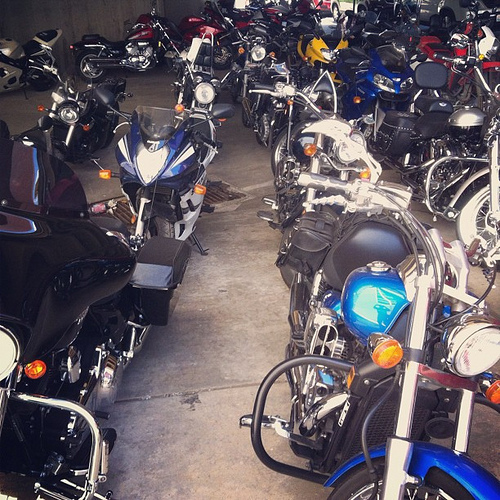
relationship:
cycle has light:
[94, 88, 237, 257] [336, 136, 366, 163]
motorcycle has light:
[214, 36, 282, 97] [312, 47, 346, 63]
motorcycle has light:
[74, 21, 179, 70] [187, 82, 226, 105]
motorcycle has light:
[35, 87, 125, 145] [54, 103, 80, 126]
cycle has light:
[94, 88, 237, 257] [187, 82, 226, 105]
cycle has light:
[94, 88, 237, 257] [245, 44, 270, 64]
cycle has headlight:
[94, 88, 237, 257] [342, 135, 356, 171]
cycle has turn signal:
[94, 88, 237, 257] [93, 167, 116, 185]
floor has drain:
[233, 130, 251, 153] [212, 178, 251, 207]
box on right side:
[276, 211, 336, 278] [341, 68, 362, 95]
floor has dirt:
[233, 130, 251, 153] [214, 236, 245, 282]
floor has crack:
[233, 130, 251, 153] [244, 174, 262, 195]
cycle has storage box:
[94, 88, 237, 257] [377, 98, 422, 153]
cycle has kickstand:
[94, 88, 237, 257] [191, 239, 211, 259]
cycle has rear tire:
[94, 88, 237, 257] [74, 49, 108, 78]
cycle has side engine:
[94, 88, 237, 257] [431, 141, 465, 170]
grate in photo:
[200, 177, 221, 216] [11, 8, 497, 489]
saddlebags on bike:
[401, 108, 450, 137] [9, 25, 69, 91]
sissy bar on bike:
[283, 168, 386, 206] [9, 25, 69, 91]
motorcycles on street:
[87, 29, 423, 204] [219, 133, 260, 174]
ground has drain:
[138, 77, 173, 100] [112, 180, 248, 226]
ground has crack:
[138, 77, 173, 100] [244, 174, 262, 195]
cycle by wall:
[94, 88, 237, 257] [65, 10, 110, 24]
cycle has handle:
[94, 88, 237, 257] [247, 87, 274, 97]